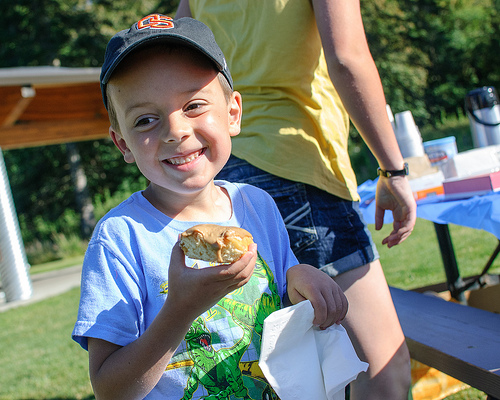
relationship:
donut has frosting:
[180, 226, 253, 263] [181, 224, 248, 244]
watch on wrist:
[379, 163, 409, 177] [374, 149, 409, 181]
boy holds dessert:
[72, 15, 347, 399] [180, 226, 253, 263]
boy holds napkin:
[72, 15, 347, 399] [256, 299, 372, 398]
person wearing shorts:
[177, 0, 413, 398] [213, 148, 380, 277]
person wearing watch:
[177, 0, 413, 398] [379, 163, 409, 177]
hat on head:
[99, 14, 234, 110] [102, 12, 242, 192]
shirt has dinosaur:
[70, 180, 301, 400] [182, 316, 253, 396]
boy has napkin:
[72, 15, 347, 399] [256, 299, 372, 398]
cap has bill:
[99, 14, 234, 110] [108, 34, 221, 69]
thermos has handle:
[461, 86, 499, 147] [471, 112, 499, 127]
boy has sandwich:
[72, 15, 347, 399] [180, 226, 253, 263]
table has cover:
[341, 168, 498, 399] [353, 171, 499, 235]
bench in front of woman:
[380, 284, 497, 399] [177, 0, 413, 398]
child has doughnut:
[72, 15, 347, 399] [180, 226, 253, 263]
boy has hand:
[72, 15, 347, 399] [285, 264, 347, 329]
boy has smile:
[72, 15, 347, 399] [162, 145, 209, 165]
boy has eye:
[72, 15, 347, 399] [187, 99, 208, 113]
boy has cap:
[72, 15, 347, 399] [99, 14, 234, 110]